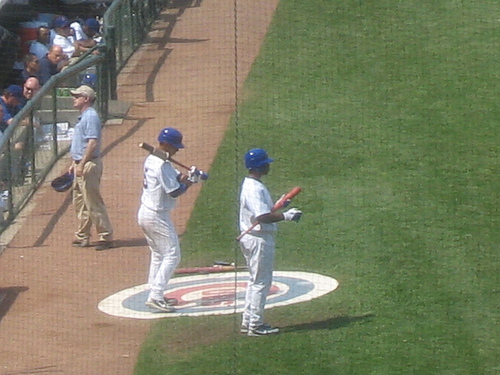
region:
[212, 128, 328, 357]
this is a baseball player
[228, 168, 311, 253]
this is a bat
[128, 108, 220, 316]
man holding a baseball bat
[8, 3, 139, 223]
people in the dugout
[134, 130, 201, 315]
baseball player wearing blue and white uniform with bat on his right hand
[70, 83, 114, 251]
man wearing light blue t-shirt and khaki pants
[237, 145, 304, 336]
man wearing blue and white uniform with bat under his arm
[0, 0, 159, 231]
large dark green fence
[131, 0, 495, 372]
green grass on basebal field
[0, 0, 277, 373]
light brown dusty field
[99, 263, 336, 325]
red blue and white symbol on the ground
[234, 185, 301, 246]
orange bat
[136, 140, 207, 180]
light brown wooden bat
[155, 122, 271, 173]
the blue helmets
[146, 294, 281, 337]
a pair sneakers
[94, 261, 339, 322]
symbol on the ground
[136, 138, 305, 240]
a wooden bat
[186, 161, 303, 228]
gloves on hands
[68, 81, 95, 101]
a tan cap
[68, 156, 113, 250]
a pair of khakis pants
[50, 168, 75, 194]
the catchers glove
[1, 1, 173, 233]
the sideline fence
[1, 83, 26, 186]
baseball player in dugout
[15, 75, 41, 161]
baseball player in dugout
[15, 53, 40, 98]
baseball player in dugout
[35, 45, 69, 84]
baseball player in dugout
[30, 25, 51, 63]
baseball player in dugout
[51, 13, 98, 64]
baseball player in dugout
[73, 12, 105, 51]
baseball player in dugout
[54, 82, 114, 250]
man wearing tan baseball cap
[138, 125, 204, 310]
baseball player wearing blue helmet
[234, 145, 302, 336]
baseball player wearing blue helmet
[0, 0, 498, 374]
the interior of a baseball stadium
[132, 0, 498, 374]
the green grass of the baseball field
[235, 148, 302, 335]
a baseball player getting ready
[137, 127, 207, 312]
a baseball player getting ready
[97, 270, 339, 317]
a baseball team logo on the field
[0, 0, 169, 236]
a green fence on the side of the field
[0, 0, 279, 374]
a brown dirt area on the side of the field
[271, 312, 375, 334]
a baseball player's shadow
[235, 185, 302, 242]
a baseball bat held by a player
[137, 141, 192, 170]
a baseball bat held by a player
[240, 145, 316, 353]
man wearing blue helmet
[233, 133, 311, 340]
man wearing white shirt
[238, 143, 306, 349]
man wearing white pants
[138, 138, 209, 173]
The baseball player is holding a bat.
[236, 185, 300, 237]
The baseball player is holding a bat.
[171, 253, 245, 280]
There is a baseball bat on the ground.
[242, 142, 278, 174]
blue sports safety helmet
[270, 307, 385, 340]
shadow of man on grass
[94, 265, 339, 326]
cubs logo on grass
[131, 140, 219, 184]
baseball bat leaning on shoulder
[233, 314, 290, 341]
black and white footwear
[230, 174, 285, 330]
man's white sports uniform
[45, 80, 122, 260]
man wearing khaki pants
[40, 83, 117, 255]
man wearing baseball cap